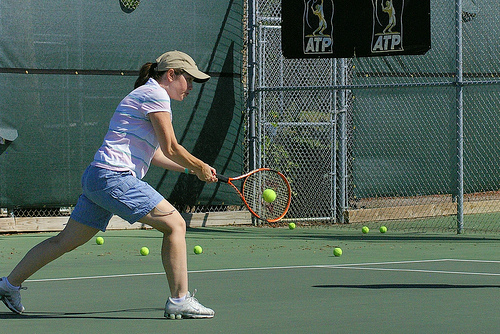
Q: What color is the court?
A: Green.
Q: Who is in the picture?
A: A tennis player.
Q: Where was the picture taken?
A: On a tennis court.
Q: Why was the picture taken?
A: To capture the woman.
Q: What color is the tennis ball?
A: Yellow.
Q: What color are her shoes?
A: White.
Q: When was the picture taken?
A: In the daytime.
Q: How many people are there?
A: 1.